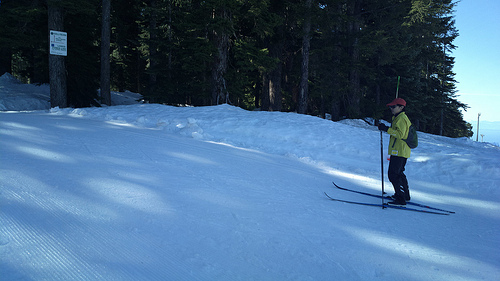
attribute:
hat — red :
[378, 94, 413, 113]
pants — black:
[379, 152, 409, 204]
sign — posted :
[48, 29, 67, 56]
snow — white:
[0, 73, 498, 278]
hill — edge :
[2, 107, 499, 272]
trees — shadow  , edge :
[7, 5, 474, 135]